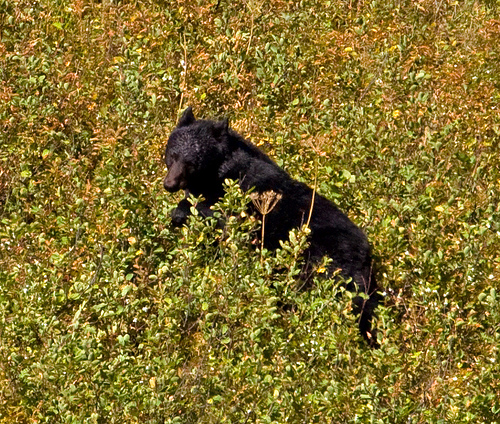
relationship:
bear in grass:
[148, 108, 388, 348] [6, 4, 499, 422]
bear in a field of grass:
[162, 105, 383, 351] [88, 289, 279, 424]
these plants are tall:
[64, 96, 153, 322] [28, 154, 84, 199]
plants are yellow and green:
[12, 357, 437, 424] [32, 243, 77, 273]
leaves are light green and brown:
[0, 0, 500, 424] [29, 349, 73, 424]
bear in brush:
[162, 105, 383, 351] [255, 338, 467, 424]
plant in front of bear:
[44, 80, 144, 273] [212, 158, 413, 250]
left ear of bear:
[211, 117, 230, 149] [163, 148, 424, 253]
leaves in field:
[28, 241, 201, 361] [23, 306, 296, 424]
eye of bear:
[155, 137, 179, 150] [116, 116, 367, 327]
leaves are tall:
[0, 0, 500, 424] [240, 312, 264, 355]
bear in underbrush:
[148, 108, 388, 348] [0, 2, 498, 420]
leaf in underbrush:
[477, 285, 486, 302] [0, 2, 498, 420]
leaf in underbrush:
[200, 300, 213, 310] [0, 2, 498, 420]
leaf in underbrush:
[409, 54, 424, 72] [0, 2, 498, 420]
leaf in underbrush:
[20, 166, 33, 179] [0, 2, 498, 420]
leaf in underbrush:
[115, 330, 129, 347] [0, 2, 498, 420]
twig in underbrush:
[245, 190, 281, 266] [0, 2, 498, 420]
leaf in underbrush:
[362, 370, 372, 386] [0, 2, 498, 420]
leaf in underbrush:
[55, 395, 68, 411] [0, 2, 498, 420]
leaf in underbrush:
[149, 89, 157, 110] [0, 2, 498, 420]